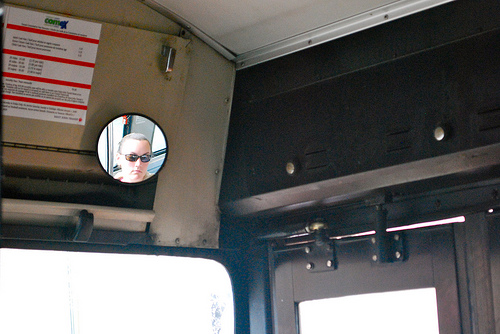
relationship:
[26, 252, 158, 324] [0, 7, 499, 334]
window on bus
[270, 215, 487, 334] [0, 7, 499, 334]
door on bus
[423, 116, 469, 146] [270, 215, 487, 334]
screws on door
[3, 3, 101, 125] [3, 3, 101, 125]
letter on letter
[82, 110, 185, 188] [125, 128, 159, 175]
reflection of passenger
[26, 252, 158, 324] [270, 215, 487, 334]
window on door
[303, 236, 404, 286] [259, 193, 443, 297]
bolts on objects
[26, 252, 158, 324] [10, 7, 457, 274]
window on bus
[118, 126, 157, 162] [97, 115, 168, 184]
face seen in reflection